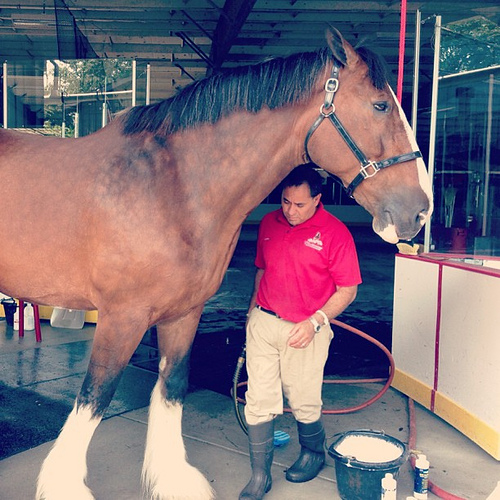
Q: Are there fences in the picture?
A: No, there are no fences.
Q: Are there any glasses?
A: No, there are no glasses.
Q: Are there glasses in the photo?
A: No, there are no glasses.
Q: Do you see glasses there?
A: No, there are no glasses.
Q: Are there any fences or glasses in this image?
A: No, there are no glasses or fences.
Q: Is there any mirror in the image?
A: No, there are no mirrors.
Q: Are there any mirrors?
A: No, there are no mirrors.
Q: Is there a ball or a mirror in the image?
A: No, there are no mirrors or balls.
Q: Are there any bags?
A: No, there are no bags.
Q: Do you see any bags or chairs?
A: No, there are no bags or chairs.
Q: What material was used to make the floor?
A: The floor is made of concrete.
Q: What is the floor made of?
A: The floor is made of concrete.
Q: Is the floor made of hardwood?
A: No, the floor is made of concrete.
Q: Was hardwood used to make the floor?
A: No, the floor is made of concrete.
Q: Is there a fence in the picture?
A: No, there are no fences.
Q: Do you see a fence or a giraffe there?
A: No, there are no fences or giraffes.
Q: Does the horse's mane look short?
A: Yes, the mane is short.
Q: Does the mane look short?
A: Yes, the mane is short.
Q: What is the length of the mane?
A: The mane is short.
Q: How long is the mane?
A: The mane is short.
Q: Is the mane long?
A: No, the mane is short.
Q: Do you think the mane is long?
A: No, the mane is short.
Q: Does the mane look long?
A: No, the mane is short.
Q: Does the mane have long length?
A: No, the mane is short.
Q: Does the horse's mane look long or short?
A: The mane is short.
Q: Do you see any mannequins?
A: No, there are no mannequins.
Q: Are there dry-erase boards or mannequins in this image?
A: No, there are no mannequins or dry-erase boards.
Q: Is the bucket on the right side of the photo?
A: Yes, the bucket is on the right of the image.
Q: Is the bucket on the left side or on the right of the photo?
A: The bucket is on the right of the image.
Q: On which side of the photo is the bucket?
A: The bucket is on the right of the image.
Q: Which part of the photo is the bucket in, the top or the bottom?
A: The bucket is in the bottom of the image.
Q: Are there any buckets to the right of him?
A: Yes, there is a bucket to the right of the man.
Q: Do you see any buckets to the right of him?
A: Yes, there is a bucket to the right of the man.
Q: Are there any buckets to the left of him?
A: No, the bucket is to the right of the man.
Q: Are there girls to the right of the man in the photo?
A: No, there is a bucket to the right of the man.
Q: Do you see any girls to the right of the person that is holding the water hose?
A: No, there is a bucket to the right of the man.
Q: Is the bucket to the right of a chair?
A: No, the bucket is to the right of the man.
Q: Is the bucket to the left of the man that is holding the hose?
A: No, the bucket is to the right of the man.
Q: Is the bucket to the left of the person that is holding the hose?
A: No, the bucket is to the right of the man.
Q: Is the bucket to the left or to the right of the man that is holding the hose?
A: The bucket is to the right of the man.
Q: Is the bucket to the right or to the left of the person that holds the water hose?
A: The bucket is to the right of the man.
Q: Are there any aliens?
A: No, there are no aliens.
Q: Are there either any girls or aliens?
A: No, there are no aliens or girls.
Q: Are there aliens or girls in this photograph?
A: No, there are no aliens or girls.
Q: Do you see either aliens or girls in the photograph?
A: No, there are no aliens or girls.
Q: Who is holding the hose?
A: The man is holding the hose.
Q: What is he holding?
A: The man is holding the water hose.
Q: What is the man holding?
A: The man is holding the water hose.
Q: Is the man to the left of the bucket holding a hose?
A: Yes, the man is holding a hose.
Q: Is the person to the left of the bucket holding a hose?
A: Yes, the man is holding a hose.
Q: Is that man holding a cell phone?
A: No, the man is holding a hose.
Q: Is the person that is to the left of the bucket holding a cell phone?
A: No, the man is holding a hose.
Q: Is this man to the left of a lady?
A: No, the man is to the left of the bucket.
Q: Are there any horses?
A: Yes, there is a horse.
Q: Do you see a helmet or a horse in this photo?
A: Yes, there is a horse.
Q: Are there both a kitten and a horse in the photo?
A: No, there is a horse but no kittens.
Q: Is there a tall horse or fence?
A: Yes, there is a tall horse.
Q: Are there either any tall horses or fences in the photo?
A: Yes, there is a tall horse.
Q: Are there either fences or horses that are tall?
A: Yes, the horse is tall.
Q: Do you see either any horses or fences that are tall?
A: Yes, the horse is tall.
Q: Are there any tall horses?
A: Yes, there is a tall horse.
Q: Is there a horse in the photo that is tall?
A: Yes, there is a horse that is tall.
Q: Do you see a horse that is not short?
A: Yes, there is a tall horse.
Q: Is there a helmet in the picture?
A: No, there are no helmets.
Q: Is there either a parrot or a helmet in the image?
A: No, there are no helmets or parrots.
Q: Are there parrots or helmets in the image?
A: No, there are no helmets or parrots.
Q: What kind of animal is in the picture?
A: The animal is a horse.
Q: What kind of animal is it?
A: The animal is a horse.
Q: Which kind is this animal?
A: This is a horse.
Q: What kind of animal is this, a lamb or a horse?
A: This is a horse.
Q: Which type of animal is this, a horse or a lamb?
A: This is a horse.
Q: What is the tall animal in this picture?
A: The animal is a horse.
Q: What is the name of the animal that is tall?
A: The animal is a horse.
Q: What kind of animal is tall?
A: The animal is a horse.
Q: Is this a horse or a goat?
A: This is a horse.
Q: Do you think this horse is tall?
A: Yes, the horse is tall.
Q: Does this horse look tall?
A: Yes, the horse is tall.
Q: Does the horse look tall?
A: Yes, the horse is tall.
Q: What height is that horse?
A: The horse is tall.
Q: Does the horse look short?
A: No, the horse is tall.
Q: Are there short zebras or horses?
A: No, there is a horse but it is tall.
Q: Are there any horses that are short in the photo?
A: No, there is a horse but it is tall.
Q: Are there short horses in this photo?
A: No, there is a horse but it is tall.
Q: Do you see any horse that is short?
A: No, there is a horse but it is tall.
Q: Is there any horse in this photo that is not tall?
A: No, there is a horse but it is tall.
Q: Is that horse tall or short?
A: The horse is tall.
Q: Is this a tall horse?
A: Yes, this is a tall horse.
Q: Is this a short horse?
A: No, this is a tall horse.